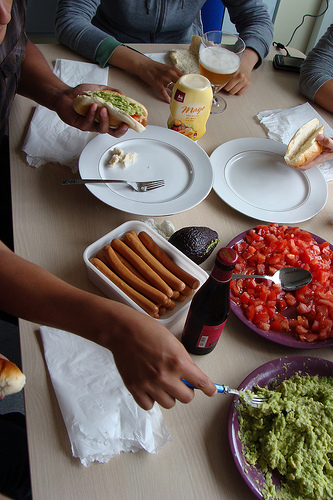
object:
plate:
[74, 120, 214, 216]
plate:
[204, 136, 330, 226]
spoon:
[226, 262, 316, 296]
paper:
[19, 55, 111, 176]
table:
[4, 36, 332, 500]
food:
[233, 373, 332, 495]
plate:
[225, 354, 333, 500]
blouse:
[49, 1, 278, 70]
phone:
[270, 52, 313, 74]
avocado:
[169, 226, 221, 265]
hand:
[102, 312, 217, 411]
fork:
[165, 374, 280, 410]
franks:
[86, 228, 199, 318]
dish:
[82, 220, 211, 333]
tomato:
[231, 221, 333, 343]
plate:
[215, 222, 331, 352]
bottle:
[180, 243, 240, 356]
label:
[194, 317, 228, 355]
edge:
[23, 149, 87, 176]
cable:
[272, 1, 332, 52]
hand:
[57, 84, 130, 137]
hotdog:
[70, 83, 153, 131]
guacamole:
[74, 87, 150, 134]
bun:
[281, 115, 331, 171]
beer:
[197, 46, 242, 91]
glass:
[195, 29, 245, 118]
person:
[298, 24, 333, 117]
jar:
[165, 72, 214, 141]